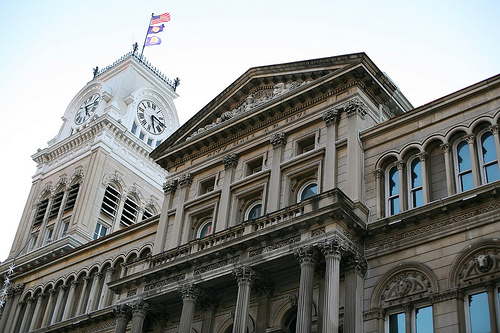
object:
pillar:
[229, 264, 250, 333]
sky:
[1, 0, 499, 261]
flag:
[141, 10, 174, 48]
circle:
[150, 24, 162, 35]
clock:
[134, 93, 167, 136]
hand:
[151, 120, 157, 136]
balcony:
[105, 187, 370, 310]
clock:
[70, 94, 99, 126]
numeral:
[152, 101, 156, 111]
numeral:
[144, 100, 154, 110]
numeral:
[135, 119, 150, 129]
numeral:
[147, 123, 153, 132]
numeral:
[152, 122, 158, 135]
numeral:
[141, 116, 148, 131]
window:
[376, 148, 401, 214]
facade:
[150, 48, 390, 265]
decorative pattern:
[367, 260, 441, 312]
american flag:
[149, 11, 171, 24]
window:
[470, 115, 498, 198]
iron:
[173, 72, 181, 92]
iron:
[130, 40, 139, 56]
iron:
[92, 63, 99, 78]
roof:
[245, 52, 373, 68]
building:
[0, 38, 182, 270]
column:
[109, 251, 371, 332]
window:
[90, 181, 175, 236]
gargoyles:
[372, 263, 437, 308]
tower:
[0, 0, 500, 333]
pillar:
[320, 257, 341, 333]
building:
[0, 0, 499, 333]